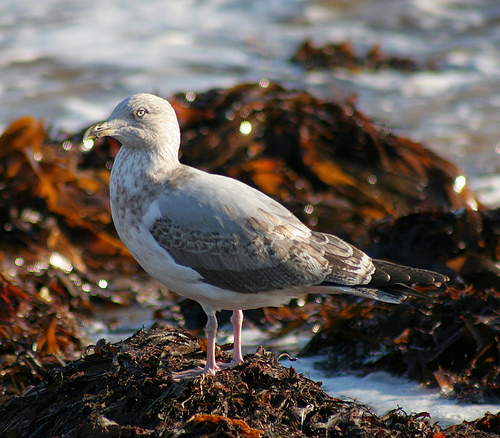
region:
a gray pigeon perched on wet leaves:
[43, 77, 439, 405]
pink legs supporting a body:
[201, 314, 246, 376]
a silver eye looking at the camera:
[131, 98, 149, 120]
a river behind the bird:
[67, 2, 214, 74]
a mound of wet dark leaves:
[34, 373, 321, 425]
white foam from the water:
[358, 371, 406, 401]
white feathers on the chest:
[133, 236, 165, 259]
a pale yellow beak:
[79, 118, 107, 140]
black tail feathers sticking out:
[377, 270, 429, 288]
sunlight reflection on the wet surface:
[233, 110, 273, 143]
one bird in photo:
[51, 65, 418, 328]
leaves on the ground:
[23, 248, 101, 363]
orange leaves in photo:
[18, 244, 100, 366]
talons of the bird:
[158, 326, 263, 408]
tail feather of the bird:
[301, 248, 452, 381]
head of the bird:
[72, 61, 182, 179]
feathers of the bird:
[171, 151, 305, 298]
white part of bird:
[118, 206, 182, 308]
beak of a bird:
[86, 108, 126, 148]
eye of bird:
[126, 104, 159, 129]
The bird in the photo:
[81, 85, 451, 380]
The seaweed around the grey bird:
[0, 36, 499, 436]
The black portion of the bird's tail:
[368, 255, 453, 305]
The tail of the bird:
[308, 226, 452, 326]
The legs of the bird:
[166, 306, 246, 380]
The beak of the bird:
[82, 120, 113, 141]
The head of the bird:
[78, 88, 183, 150]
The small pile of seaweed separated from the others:
[291, 29, 435, 76]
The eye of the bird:
[133, 105, 150, 118]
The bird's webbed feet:
[164, 356, 245, 383]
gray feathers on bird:
[135, 149, 316, 346]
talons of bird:
[157, 348, 259, 406]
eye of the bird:
[126, 92, 163, 137]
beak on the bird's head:
[83, 112, 118, 164]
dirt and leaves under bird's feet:
[196, 375, 286, 437]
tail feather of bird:
[348, 216, 441, 329]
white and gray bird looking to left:
[81, 70, 263, 270]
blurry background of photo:
[7, 11, 167, 91]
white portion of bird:
[129, 232, 189, 299]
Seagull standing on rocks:
[85, 98, 454, 396]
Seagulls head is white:
[96, 84, 206, 162]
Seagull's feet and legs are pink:
[163, 314, 277, 389]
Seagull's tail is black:
[366, 248, 471, 308]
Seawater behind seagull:
[281, 345, 498, 435]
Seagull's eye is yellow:
[131, 104, 152, 119]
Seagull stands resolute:
[66, 78, 475, 389]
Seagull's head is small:
[68, 98, 203, 153]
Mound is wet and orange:
[191, 90, 471, 205]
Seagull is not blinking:
[97, 98, 180, 131]